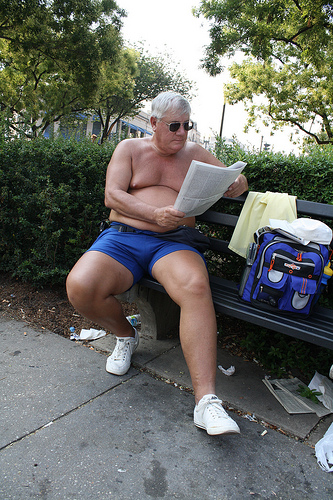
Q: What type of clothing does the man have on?
A: A pair of shorts.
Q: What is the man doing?
A: Reading a newspaper.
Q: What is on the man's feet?
A: A pair of sneakers.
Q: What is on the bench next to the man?
A: A blue and grey bag.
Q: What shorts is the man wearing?
A: Blue shorts.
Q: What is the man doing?
A: Reading a news paper.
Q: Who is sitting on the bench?
A: The man.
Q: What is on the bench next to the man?
A: A bag.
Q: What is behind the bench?
A: Trees.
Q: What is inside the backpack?
A: The man's contents.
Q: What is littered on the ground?
A: Trash.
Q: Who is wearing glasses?
A: The man.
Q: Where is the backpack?
A: On the bench.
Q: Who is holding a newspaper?
A: The man.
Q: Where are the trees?
A: Behind the man.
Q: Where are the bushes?
A: Behind the man.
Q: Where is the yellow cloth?
A: The back of the bench.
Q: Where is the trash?
A: On the ground.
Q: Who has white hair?
A: The man.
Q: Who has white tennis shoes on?
A: The man.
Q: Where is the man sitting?
A: On the bench.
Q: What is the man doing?
A: Reading a paper.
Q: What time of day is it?
A: Daytime.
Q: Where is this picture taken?
A: Park.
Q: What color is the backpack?
A: Blue.